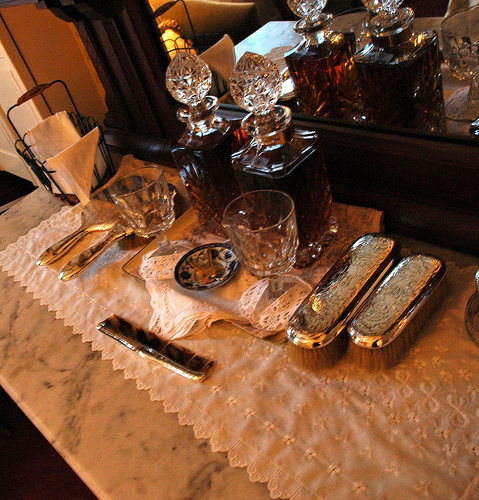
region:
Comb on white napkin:
[97, 311, 215, 381]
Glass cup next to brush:
[223, 187, 315, 332]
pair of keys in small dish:
[188, 248, 227, 282]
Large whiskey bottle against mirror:
[228, 49, 338, 267]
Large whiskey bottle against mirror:
[163, 50, 236, 237]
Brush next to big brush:
[347, 251, 450, 371]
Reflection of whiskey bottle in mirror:
[353, 0, 446, 133]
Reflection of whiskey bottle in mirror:
[281, 0, 359, 125]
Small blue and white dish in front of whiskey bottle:
[174, 241, 238, 290]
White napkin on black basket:
[24, 110, 102, 205]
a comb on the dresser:
[93, 291, 225, 404]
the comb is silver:
[79, 308, 219, 387]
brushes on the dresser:
[275, 240, 433, 351]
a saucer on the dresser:
[151, 229, 238, 287]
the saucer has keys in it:
[153, 237, 243, 296]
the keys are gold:
[183, 239, 234, 283]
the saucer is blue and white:
[174, 237, 237, 299]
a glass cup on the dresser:
[205, 175, 295, 280]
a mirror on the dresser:
[117, 0, 466, 258]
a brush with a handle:
[50, 184, 158, 292]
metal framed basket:
[10, 78, 114, 208]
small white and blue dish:
[175, 243, 237, 288]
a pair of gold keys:
[190, 249, 220, 281]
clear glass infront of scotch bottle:
[224, 191, 310, 322]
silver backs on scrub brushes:
[292, 232, 442, 345]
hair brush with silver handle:
[58, 184, 165, 290]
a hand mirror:
[37, 165, 161, 267]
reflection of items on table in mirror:
[145, 0, 476, 147]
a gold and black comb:
[97, 316, 215, 381]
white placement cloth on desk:
[4, 147, 478, 494]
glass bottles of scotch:
[164, 43, 336, 264]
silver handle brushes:
[291, 228, 449, 365]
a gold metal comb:
[96, 315, 213, 383]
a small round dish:
[178, 244, 230, 289]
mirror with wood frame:
[143, 0, 478, 151]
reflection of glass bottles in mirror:
[144, 0, 476, 140]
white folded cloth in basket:
[27, 111, 98, 203]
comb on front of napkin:
[86, 294, 216, 395]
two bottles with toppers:
[167, 45, 348, 273]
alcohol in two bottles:
[164, 45, 337, 270]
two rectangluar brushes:
[282, 225, 440, 388]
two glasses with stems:
[117, 170, 332, 341]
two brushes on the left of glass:
[39, 141, 185, 310]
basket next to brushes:
[20, 52, 107, 193]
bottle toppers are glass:
[153, 47, 302, 126]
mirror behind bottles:
[97, 12, 477, 193]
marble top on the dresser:
[6, 180, 411, 497]